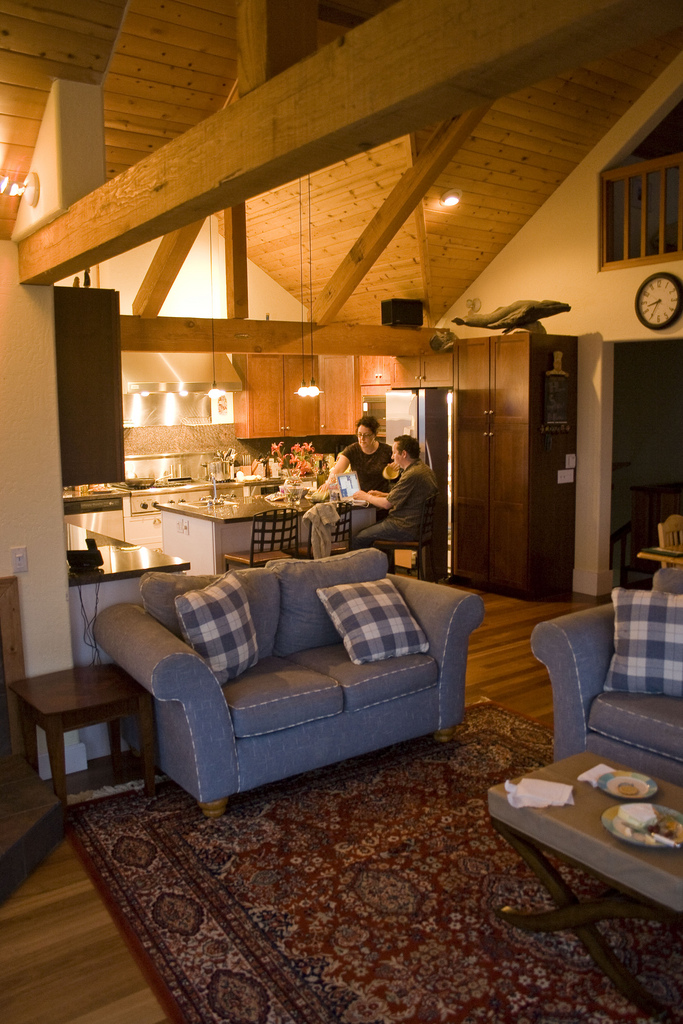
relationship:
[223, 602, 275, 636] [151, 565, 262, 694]
square on a pillow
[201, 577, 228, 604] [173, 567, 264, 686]
square on a pillow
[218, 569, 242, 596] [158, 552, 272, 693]
square on a pillow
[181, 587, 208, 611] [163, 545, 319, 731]
square on a pillow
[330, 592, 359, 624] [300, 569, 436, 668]
square on a pillow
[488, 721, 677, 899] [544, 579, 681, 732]
coffee table by couch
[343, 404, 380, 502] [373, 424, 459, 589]
woman next to man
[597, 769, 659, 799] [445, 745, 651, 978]
plate on table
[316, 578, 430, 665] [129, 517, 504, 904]
pillow on couch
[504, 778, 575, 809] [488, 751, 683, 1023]
napkin on coffee table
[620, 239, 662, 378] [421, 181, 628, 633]
clock on wall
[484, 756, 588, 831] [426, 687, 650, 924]
napkin on table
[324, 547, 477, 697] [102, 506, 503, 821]
pillow on couch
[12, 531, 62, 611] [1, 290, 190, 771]
switch on wall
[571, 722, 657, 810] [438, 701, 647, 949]
plate on table